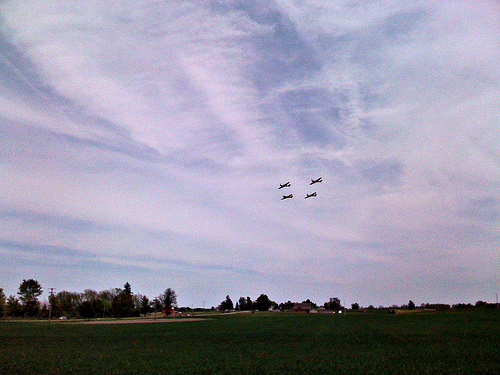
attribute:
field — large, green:
[3, 307, 499, 373]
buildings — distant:
[289, 302, 320, 312]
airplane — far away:
[308, 176, 323, 187]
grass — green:
[248, 350, 285, 358]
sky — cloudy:
[6, 14, 463, 168]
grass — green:
[358, 324, 429, 361]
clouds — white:
[0, 0, 499, 302]